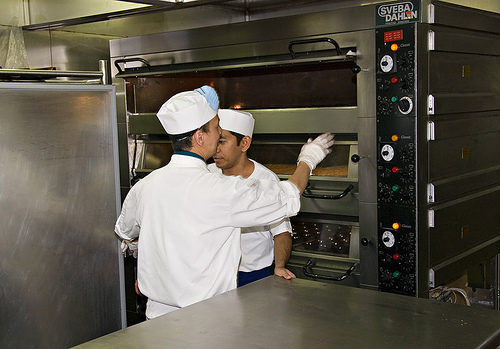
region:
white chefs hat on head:
[156, 82, 221, 138]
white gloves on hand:
[297, 129, 338, 175]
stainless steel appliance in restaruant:
[103, 30, 487, 342]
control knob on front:
[393, 94, 415, 115]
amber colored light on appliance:
[387, 220, 402, 232]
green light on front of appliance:
[388, 182, 401, 189]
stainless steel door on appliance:
[0, 78, 133, 343]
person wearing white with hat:
[110, 80, 337, 315]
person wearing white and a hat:
[202, 107, 294, 282]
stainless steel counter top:
[26, 267, 491, 347]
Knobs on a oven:
[371, 5, 423, 300]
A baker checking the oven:
[112, 83, 334, 319]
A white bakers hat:
[154, 83, 219, 134]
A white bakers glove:
[296, 131, 338, 176]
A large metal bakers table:
[67, 272, 498, 347]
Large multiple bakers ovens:
[107, 1, 499, 306]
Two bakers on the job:
[115, 84, 336, 321]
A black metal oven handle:
[285, 37, 347, 63]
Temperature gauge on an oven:
[379, 142, 396, 164]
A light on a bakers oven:
[388, 40, 402, 52]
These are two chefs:
[145, 126, 316, 301]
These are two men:
[133, 134, 250, 229]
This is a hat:
[144, 99, 205, 144]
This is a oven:
[277, 73, 490, 313]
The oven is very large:
[388, 124, 461, 262]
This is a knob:
[382, 144, 409, 283]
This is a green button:
[379, 173, 393, 190]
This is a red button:
[378, 160, 396, 165]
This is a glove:
[269, 139, 366, 191]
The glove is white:
[298, 140, 305, 161]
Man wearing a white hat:
[155, 81, 225, 165]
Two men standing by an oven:
[109, 79, 336, 319]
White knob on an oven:
[379, 140, 394, 163]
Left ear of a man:
[237, 133, 253, 154]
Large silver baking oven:
[106, 1, 498, 328]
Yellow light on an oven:
[391, 219, 401, 230]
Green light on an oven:
[388, 181, 399, 192]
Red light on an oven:
[389, 74, 399, 83]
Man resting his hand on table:
[203, 103, 298, 288]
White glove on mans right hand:
[292, 126, 336, 173]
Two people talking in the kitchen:
[136, 86, 321, 308]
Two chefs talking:
[117, 92, 349, 339]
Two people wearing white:
[116, 80, 330, 328]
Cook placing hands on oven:
[105, 93, 344, 330]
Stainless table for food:
[242, 280, 497, 342]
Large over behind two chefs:
[101, 39, 441, 301]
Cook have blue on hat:
[125, 92, 339, 326]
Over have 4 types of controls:
[131, 23, 458, 300]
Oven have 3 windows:
[125, 53, 375, 265]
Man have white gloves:
[105, 18, 428, 319]